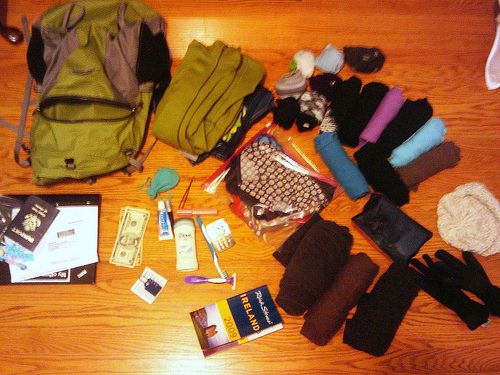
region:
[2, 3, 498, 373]
items laid out for a trip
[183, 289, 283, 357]
travel brochure for ireland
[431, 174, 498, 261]
tan colored cloth hat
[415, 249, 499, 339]
pair of black gloves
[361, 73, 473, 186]
group of different colored socks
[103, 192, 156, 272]
american paper money a five on top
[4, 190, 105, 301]
passport and other papers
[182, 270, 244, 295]
purple and white razor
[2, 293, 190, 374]
grained wooden floor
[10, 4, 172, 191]
olive backpack with open zipper compartment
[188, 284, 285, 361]
ireland tour guide book 2009 edition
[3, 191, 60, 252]
american passport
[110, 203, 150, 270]
small pile of american money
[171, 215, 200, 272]
container of dove deodorant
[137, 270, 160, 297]
small combination lock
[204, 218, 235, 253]
package of small yellow pills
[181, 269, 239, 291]
purple and white women's razor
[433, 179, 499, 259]
white lacy hat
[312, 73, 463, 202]
collection of rolled shirts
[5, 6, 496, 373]
items on the floor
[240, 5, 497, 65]
the floor is wooden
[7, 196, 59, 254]
the passport on the paper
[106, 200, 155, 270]
the money on the floor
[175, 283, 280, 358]
the guide to ireland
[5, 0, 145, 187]
green backpack on the floor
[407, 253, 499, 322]
gloves on the floor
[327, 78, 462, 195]
clothes on the floor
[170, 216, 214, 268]
deodorant on the floor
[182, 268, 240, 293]
razor on the floor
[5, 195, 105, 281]
passport and other information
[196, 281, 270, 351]
travel guide to ireland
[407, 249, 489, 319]
a pair of black gloves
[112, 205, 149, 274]
money laying on the table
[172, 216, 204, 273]
a stick of deodorant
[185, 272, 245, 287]
a razor for shaving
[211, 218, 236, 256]
medication laying on the table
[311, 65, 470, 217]
rolled up clothes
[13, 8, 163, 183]
a green backpack on the table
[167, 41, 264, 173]
folded up bottoms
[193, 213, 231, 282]
a blue and white toothbrush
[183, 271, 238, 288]
a purple and white razor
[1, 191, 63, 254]
a passport on top of a paper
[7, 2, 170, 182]
a green, grey, and black backpack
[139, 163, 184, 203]
a small blue jewelry bag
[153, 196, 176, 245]
a small tube of toothpaste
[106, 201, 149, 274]
two paper bills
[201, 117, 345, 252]
a plastic ziploc bag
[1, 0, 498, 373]
a light brown hardwood floor